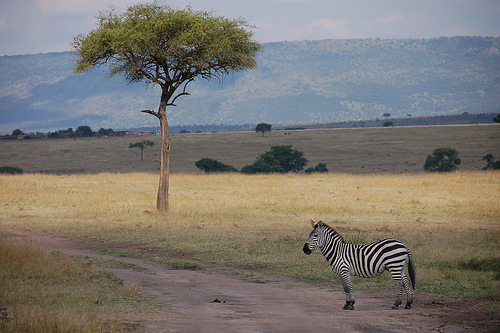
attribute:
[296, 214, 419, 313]
zebra — white, black, striped, looking, standing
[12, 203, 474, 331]
road — sandy, dirt path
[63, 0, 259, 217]
tree — lone, tall, skinny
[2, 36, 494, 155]
hill — background, distance, vegetation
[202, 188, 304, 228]
grass — dry, yellow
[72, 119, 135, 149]
house — distance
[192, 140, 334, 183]
bushes — clustered